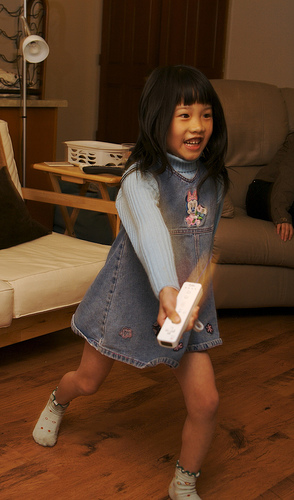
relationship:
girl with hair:
[30, 65, 243, 498] [126, 65, 242, 195]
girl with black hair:
[30, 65, 243, 498] [126, 65, 242, 195]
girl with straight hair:
[30, 65, 243, 498] [126, 65, 242, 195]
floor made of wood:
[4, 310, 293, 499] [243, 382, 289, 447]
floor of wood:
[4, 310, 293, 499] [243, 382, 289, 447]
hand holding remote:
[157, 288, 181, 327] [153, 282, 213, 347]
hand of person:
[157, 288, 181, 327] [30, 65, 243, 498]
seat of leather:
[0, 120, 114, 345] [3, 232, 113, 327]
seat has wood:
[0, 120, 114, 345] [4, 304, 90, 351]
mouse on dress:
[185, 190, 206, 230] [68, 145, 236, 368]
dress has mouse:
[68, 145, 236, 368] [185, 190, 206, 230]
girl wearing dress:
[30, 65, 243, 498] [68, 145, 236, 368]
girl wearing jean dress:
[30, 65, 243, 498] [68, 145, 236, 368]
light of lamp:
[24, 35, 50, 64] [19, 13, 49, 188]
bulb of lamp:
[30, 42, 42, 58] [19, 13, 49, 188]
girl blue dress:
[30, 65, 243, 498] [68, 145, 236, 368]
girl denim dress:
[30, 65, 243, 498] [68, 145, 236, 368]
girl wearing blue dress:
[30, 65, 243, 498] [68, 145, 236, 368]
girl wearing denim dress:
[30, 65, 243, 498] [68, 145, 236, 368]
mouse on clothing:
[185, 190, 206, 230] [118, 161, 223, 284]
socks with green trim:
[29, 391, 211, 499] [49, 388, 70, 413]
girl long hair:
[30, 65, 243, 498] [126, 65, 242, 195]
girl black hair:
[30, 65, 243, 498] [126, 65, 242, 195]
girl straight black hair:
[30, 65, 243, 498] [126, 65, 242, 195]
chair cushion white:
[0, 120, 114, 345] [21, 246, 57, 274]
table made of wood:
[39, 160, 121, 239] [243, 382, 289, 447]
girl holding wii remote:
[30, 65, 243, 498] [153, 282, 213, 347]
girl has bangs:
[30, 65, 243, 498] [170, 78, 212, 105]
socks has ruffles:
[29, 391, 211, 499] [171, 462, 200, 482]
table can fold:
[39, 160, 121, 239] [41, 171, 113, 191]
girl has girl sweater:
[30, 65, 243, 498] [118, 168, 180, 291]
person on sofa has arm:
[243, 101, 294, 236] [270, 153, 293, 219]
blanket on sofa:
[251, 179, 292, 217] [210, 78, 292, 305]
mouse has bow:
[185, 190, 206, 230] [188, 188, 198, 202]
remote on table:
[153, 282, 213, 347] [39, 160, 121, 239]